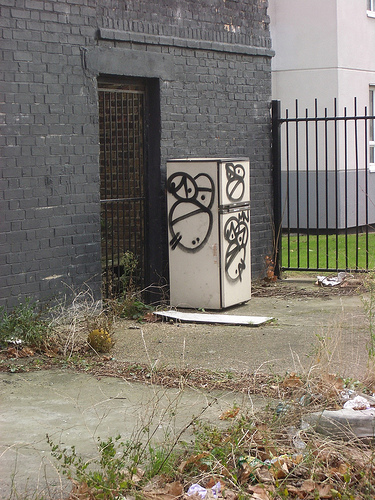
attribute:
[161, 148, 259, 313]
refrigerator — discarded, white, old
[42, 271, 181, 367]
weeds — overgrown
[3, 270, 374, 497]
sidewalk — outdoors, concrete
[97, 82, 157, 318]
grate — metal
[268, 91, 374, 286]
gate — iron, black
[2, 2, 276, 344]
wall — brick, gray, painted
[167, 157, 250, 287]
graffiti — black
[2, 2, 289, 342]
building — brick, grey, dark blue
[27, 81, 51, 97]
brick — grey, gray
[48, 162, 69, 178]
brick — grey, gray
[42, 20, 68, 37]
brick — grey, gray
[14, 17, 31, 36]
brick — grey, blue, gray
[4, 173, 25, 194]
brick — grey, gray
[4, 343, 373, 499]
leaves — dead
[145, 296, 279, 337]
cardboard — flat, white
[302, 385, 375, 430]
bag — yellow, plastic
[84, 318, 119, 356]
ball — yellow, old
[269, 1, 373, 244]
building — adjacent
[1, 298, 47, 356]
shrub — green, scraggly